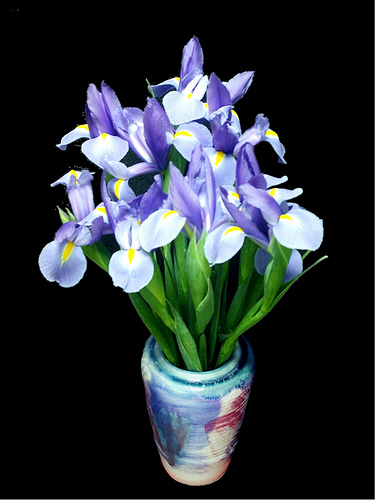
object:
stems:
[85, 238, 293, 371]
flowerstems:
[55, 205, 329, 372]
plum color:
[208, 413, 236, 449]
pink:
[192, 469, 210, 481]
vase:
[140, 333, 255, 487]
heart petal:
[162, 88, 207, 126]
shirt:
[48, 159, 95, 229]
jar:
[140, 333, 255, 487]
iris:
[272, 203, 324, 252]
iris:
[137, 208, 186, 253]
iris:
[109, 249, 155, 293]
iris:
[38, 240, 87, 288]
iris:
[81, 133, 129, 169]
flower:
[201, 190, 261, 268]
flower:
[38, 35, 324, 295]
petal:
[109, 248, 154, 293]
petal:
[272, 202, 324, 251]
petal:
[202, 223, 244, 267]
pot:
[140, 335, 257, 486]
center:
[128, 248, 135, 265]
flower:
[108, 249, 154, 293]